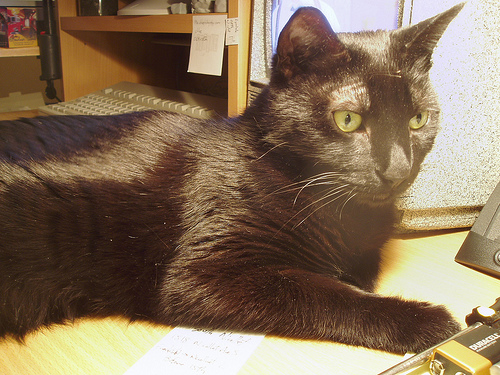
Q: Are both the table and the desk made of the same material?
A: Yes, both the table and the desk are made of wood.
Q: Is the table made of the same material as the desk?
A: Yes, both the table and the desk are made of wood.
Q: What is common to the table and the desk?
A: The material, both the table and the desk are wooden.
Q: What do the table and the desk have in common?
A: The material, both the table and the desk are wooden.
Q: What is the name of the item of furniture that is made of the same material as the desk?
A: The piece of furniture is a table.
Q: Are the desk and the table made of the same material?
A: Yes, both the desk and the table are made of wood.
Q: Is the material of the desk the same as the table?
A: Yes, both the desk and the table are made of wood.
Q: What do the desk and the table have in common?
A: The material, both the desk and the table are wooden.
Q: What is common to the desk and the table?
A: The material, both the desk and the table are wooden.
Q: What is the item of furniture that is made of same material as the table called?
A: The piece of furniture is a desk.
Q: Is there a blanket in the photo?
A: No, there are no blankets.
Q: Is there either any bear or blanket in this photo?
A: No, there are no blankets or bears.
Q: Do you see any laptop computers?
A: No, there are no laptop computers.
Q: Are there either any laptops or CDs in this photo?
A: No, there are no laptops or cds.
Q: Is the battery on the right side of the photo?
A: Yes, the battery is on the right of the image.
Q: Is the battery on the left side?
A: No, the battery is on the right of the image.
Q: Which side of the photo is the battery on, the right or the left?
A: The battery is on the right of the image.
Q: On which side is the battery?
A: The battery is on the right of the image.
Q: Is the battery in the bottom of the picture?
A: Yes, the battery is in the bottom of the image.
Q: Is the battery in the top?
A: No, the battery is in the bottom of the image.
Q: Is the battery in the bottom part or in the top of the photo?
A: The battery is in the bottom of the image.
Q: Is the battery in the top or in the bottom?
A: The battery is in the bottom of the image.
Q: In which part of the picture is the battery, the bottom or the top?
A: The battery is in the bottom of the image.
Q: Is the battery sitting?
A: Yes, the battery is sitting.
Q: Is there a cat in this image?
A: Yes, there is a cat.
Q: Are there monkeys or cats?
A: Yes, there is a cat.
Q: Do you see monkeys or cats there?
A: Yes, there is a cat.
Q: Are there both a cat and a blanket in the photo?
A: No, there is a cat but no blankets.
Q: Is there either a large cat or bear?
A: Yes, there is a large cat.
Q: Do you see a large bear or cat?
A: Yes, there is a large cat.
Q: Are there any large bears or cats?
A: Yes, there is a large cat.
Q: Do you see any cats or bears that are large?
A: Yes, the cat is large.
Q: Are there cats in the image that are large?
A: Yes, there is a large cat.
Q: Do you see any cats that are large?
A: Yes, there is a cat that is large.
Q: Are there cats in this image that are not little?
A: Yes, there is a large cat.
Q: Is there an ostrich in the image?
A: No, there are no ostriches.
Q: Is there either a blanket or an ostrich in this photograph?
A: No, there are no ostriches or blankets.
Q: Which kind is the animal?
A: The animal is a cat.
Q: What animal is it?
A: The animal is a cat.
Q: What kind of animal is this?
A: That is a cat.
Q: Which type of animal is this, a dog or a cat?
A: That is a cat.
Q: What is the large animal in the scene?
A: The animal is a cat.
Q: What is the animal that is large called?
A: The animal is a cat.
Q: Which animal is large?
A: The animal is a cat.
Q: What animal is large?
A: The animal is a cat.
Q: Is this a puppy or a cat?
A: This is a cat.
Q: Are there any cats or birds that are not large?
A: No, there is a cat but it is large.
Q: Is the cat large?
A: Yes, the cat is large.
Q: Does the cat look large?
A: Yes, the cat is large.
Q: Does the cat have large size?
A: Yes, the cat is large.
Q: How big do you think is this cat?
A: The cat is large.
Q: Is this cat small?
A: No, the cat is large.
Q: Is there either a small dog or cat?
A: No, there is a cat but it is large.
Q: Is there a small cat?
A: No, there is a cat but it is large.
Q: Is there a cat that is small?
A: No, there is a cat but it is large.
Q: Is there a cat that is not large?
A: No, there is a cat but it is large.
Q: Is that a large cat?
A: Yes, that is a large cat.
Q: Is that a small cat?
A: No, that is a large cat.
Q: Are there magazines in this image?
A: No, there are no magazines.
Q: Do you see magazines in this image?
A: No, there are no magazines.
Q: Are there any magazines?
A: No, there are no magazines.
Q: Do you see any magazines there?
A: No, there are no magazines.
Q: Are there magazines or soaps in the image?
A: No, there are no magazines or soaps.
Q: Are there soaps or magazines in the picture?
A: No, there are no magazines or soaps.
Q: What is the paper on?
A: The paper is on the desk.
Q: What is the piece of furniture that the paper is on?
A: The piece of furniture is a desk.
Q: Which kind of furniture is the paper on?
A: The paper is on the desk.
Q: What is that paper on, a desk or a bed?
A: The paper is on a desk.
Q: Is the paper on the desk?
A: Yes, the paper is on the desk.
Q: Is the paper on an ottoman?
A: No, the paper is on the desk.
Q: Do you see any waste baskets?
A: No, there are no waste baskets.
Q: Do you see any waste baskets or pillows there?
A: No, there are no waste baskets or pillows.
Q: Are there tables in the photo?
A: Yes, there is a table.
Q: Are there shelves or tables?
A: Yes, there is a table.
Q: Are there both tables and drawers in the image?
A: No, there is a table but no drawers.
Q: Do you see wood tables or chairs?
A: Yes, there is a wood table.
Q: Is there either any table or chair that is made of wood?
A: Yes, the table is made of wood.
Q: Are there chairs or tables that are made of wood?
A: Yes, the table is made of wood.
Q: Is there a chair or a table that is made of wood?
A: Yes, the table is made of wood.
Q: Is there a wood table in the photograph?
A: Yes, there is a wood table.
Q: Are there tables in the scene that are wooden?
A: Yes, there is a table that is wooden.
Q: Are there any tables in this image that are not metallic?
A: Yes, there is a wooden table.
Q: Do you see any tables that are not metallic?
A: Yes, there is a wooden table.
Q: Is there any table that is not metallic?
A: Yes, there is a wooden table.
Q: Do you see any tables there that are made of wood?
A: Yes, there is a table that is made of wood.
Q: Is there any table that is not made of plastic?
A: Yes, there is a table that is made of wood.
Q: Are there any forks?
A: No, there are no forks.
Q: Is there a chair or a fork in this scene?
A: No, there are no forks or chairs.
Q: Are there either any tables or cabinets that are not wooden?
A: No, there is a table but it is wooden.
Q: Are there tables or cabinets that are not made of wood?
A: No, there is a table but it is made of wood.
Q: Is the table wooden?
A: Yes, the table is wooden.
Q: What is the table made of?
A: The table is made of wood.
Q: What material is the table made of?
A: The table is made of wood.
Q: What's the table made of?
A: The table is made of wood.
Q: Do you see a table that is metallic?
A: No, there is a table but it is wooden.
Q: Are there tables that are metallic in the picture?
A: No, there is a table but it is wooden.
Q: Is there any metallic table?
A: No, there is a table but it is wooden.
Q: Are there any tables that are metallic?
A: No, there is a table but it is wooden.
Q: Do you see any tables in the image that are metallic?
A: No, there is a table but it is wooden.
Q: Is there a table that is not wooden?
A: No, there is a table but it is wooden.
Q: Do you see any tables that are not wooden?
A: No, there is a table but it is wooden.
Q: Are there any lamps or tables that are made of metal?
A: No, there is a table but it is made of wood.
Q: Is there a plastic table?
A: No, there is a table but it is made of wood.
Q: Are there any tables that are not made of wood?
A: No, there is a table but it is made of wood.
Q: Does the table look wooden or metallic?
A: The table is wooden.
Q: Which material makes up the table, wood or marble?
A: The table is made of wood.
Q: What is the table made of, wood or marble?
A: The table is made of wood.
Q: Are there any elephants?
A: No, there are no elephants.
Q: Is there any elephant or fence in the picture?
A: No, there are no elephants or fences.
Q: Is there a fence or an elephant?
A: No, there are no elephants or fences.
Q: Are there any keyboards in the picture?
A: Yes, there is a keyboard.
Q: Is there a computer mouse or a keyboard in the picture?
A: Yes, there is a keyboard.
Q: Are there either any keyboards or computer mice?
A: Yes, there is a keyboard.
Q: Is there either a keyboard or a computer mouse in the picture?
A: Yes, there is a keyboard.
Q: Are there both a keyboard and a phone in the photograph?
A: No, there is a keyboard but no phones.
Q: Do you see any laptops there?
A: No, there are no laptops.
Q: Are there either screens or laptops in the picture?
A: No, there are no laptops or screens.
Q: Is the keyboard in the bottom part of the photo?
A: No, the keyboard is in the top of the image.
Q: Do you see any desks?
A: Yes, there is a desk.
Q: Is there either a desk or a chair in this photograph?
A: Yes, there is a desk.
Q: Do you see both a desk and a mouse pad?
A: No, there is a desk but no mouse pads.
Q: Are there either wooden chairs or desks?
A: Yes, there is a wood desk.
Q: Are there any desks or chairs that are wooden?
A: Yes, the desk is wooden.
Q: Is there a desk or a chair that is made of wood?
A: Yes, the desk is made of wood.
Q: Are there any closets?
A: No, there are no closets.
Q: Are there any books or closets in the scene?
A: No, there are no closets or books.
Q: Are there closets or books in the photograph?
A: No, there are no closets or books.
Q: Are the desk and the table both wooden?
A: Yes, both the desk and the table are wooden.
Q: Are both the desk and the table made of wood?
A: Yes, both the desk and the table are made of wood.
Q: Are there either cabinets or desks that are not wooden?
A: No, there is a desk but it is wooden.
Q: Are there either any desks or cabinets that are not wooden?
A: No, there is a desk but it is wooden.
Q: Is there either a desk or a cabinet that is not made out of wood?
A: No, there is a desk but it is made of wood.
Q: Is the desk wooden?
A: Yes, the desk is wooden.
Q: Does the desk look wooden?
A: Yes, the desk is wooden.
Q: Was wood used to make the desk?
A: Yes, the desk is made of wood.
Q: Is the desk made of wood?
A: Yes, the desk is made of wood.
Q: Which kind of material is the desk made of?
A: The desk is made of wood.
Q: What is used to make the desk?
A: The desk is made of wood.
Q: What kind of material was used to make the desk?
A: The desk is made of wood.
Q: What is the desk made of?
A: The desk is made of wood.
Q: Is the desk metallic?
A: No, the desk is wooden.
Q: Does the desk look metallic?
A: No, the desk is wooden.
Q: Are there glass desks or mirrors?
A: No, there is a desk but it is wooden.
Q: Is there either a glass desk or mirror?
A: No, there is a desk but it is wooden.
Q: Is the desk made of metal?
A: No, the desk is made of wood.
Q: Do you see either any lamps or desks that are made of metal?
A: No, there is a desk but it is made of wood.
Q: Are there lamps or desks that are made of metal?
A: No, there is a desk but it is made of wood.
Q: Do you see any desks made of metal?
A: No, there is a desk but it is made of wood.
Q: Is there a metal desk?
A: No, there is a desk but it is made of wood.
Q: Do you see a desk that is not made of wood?
A: No, there is a desk but it is made of wood.